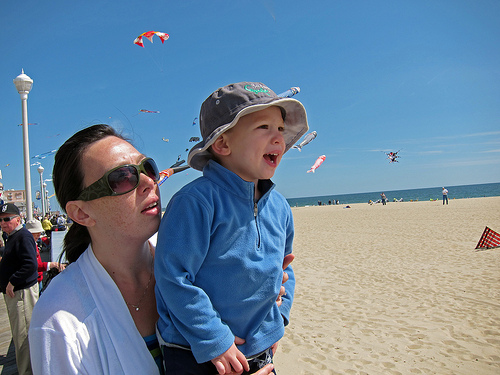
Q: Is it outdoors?
A: Yes, it is outdoors.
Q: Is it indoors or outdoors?
A: It is outdoors.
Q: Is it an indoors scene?
A: No, it is outdoors.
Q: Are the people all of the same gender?
A: No, they are both male and female.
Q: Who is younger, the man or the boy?
A: The boy is younger than the man.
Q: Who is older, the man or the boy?
A: The man is older than the boy.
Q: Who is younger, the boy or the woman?
A: The boy is younger than the woman.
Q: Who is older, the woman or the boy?
A: The woman is older than the boy.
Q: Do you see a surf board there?
A: No, there are no surfboards.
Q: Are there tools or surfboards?
A: No, there are no surfboards or tools.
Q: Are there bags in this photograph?
A: No, there are no bags.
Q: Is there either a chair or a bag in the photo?
A: No, there are no bags or chairs.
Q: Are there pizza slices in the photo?
A: No, there are no pizza slices.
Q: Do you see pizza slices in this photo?
A: No, there are no pizza slices.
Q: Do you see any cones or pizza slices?
A: No, there are no pizza slices or cones.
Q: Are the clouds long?
A: Yes, the clouds are long.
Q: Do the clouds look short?
A: No, the clouds are long.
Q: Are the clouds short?
A: No, the clouds are long.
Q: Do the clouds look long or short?
A: The clouds are long.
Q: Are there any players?
A: No, there are no players.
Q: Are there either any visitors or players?
A: No, there are no players or visitors.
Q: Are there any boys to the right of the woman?
A: Yes, there is a boy to the right of the woman.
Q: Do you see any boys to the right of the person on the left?
A: Yes, there is a boy to the right of the woman.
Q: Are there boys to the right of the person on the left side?
A: Yes, there is a boy to the right of the woman.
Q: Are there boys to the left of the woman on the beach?
A: No, the boy is to the right of the woman.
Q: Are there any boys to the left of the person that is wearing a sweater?
A: No, the boy is to the right of the woman.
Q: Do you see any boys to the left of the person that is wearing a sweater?
A: No, the boy is to the right of the woman.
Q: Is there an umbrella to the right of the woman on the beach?
A: No, there is a boy to the right of the woman.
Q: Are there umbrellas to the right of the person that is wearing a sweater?
A: No, there is a boy to the right of the woman.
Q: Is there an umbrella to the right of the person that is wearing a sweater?
A: No, there is a boy to the right of the woman.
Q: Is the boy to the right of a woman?
A: Yes, the boy is to the right of a woman.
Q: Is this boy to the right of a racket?
A: No, the boy is to the right of a woman.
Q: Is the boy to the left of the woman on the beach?
A: No, the boy is to the right of the woman.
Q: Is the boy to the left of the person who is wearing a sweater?
A: No, the boy is to the right of the woman.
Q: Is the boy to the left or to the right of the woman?
A: The boy is to the right of the woman.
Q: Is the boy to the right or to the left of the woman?
A: The boy is to the right of the woman.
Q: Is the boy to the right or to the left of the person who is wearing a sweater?
A: The boy is to the right of the woman.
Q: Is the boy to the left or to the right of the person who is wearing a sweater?
A: The boy is to the right of the woman.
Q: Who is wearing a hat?
A: The boy is wearing a hat.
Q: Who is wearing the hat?
A: The boy is wearing a hat.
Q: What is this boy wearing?
A: The boy is wearing a hat.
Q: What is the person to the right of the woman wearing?
A: The boy is wearing a hat.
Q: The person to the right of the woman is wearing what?
A: The boy is wearing a hat.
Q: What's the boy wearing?
A: The boy is wearing a hat.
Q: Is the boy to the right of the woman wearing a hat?
A: Yes, the boy is wearing a hat.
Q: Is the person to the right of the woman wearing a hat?
A: Yes, the boy is wearing a hat.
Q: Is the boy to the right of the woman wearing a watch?
A: No, the boy is wearing a hat.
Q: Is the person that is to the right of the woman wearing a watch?
A: No, the boy is wearing a hat.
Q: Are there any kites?
A: Yes, there is a kite.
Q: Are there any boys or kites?
A: Yes, there is a kite.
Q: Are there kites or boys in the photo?
A: Yes, there is a kite.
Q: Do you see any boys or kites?
A: Yes, there is a kite.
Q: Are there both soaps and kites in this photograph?
A: No, there is a kite but no soaps.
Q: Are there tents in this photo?
A: No, there are no tents.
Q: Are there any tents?
A: No, there are no tents.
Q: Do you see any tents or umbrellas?
A: No, there are no tents or umbrellas.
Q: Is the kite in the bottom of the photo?
A: No, the kite is in the top of the image.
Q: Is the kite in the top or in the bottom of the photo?
A: The kite is in the top of the image.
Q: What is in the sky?
A: The kite is in the sky.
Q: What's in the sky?
A: The kite is in the sky.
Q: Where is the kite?
A: The kite is in the sky.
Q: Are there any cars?
A: No, there are no cars.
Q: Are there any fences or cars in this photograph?
A: No, there are no cars or fences.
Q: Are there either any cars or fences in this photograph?
A: No, there are no cars or fences.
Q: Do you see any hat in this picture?
A: Yes, there is a hat.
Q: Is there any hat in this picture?
A: Yes, there is a hat.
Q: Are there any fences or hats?
A: Yes, there is a hat.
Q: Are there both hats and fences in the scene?
A: No, there is a hat but no fences.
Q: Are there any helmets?
A: No, there are no helmets.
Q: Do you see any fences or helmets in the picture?
A: No, there are no helmets or fences.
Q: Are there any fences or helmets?
A: No, there are no helmets or fences.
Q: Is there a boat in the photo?
A: No, there are no boats.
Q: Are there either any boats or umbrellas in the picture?
A: No, there are no boats or umbrellas.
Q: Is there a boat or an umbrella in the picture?
A: No, there are no boats or umbrellas.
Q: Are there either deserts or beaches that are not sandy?
A: No, there is a beach but it is sandy.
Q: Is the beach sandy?
A: Yes, the beach is sandy.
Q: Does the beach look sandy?
A: Yes, the beach is sandy.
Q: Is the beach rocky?
A: No, the beach is sandy.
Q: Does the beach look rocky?
A: No, the beach is sandy.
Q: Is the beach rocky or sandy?
A: The beach is sandy.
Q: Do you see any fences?
A: No, there are no fences.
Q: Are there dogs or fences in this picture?
A: No, there are no fences or dogs.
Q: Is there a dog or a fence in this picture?
A: No, there are no fences or dogs.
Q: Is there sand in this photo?
A: Yes, there is sand.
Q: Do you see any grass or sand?
A: Yes, there is sand.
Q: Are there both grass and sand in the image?
A: No, there is sand but no grass.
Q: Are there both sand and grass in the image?
A: No, there is sand but no grass.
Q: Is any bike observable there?
A: No, there are no bikes.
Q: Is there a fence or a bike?
A: No, there are no bikes or fences.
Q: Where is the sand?
A: The sand is on the beach.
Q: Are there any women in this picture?
A: Yes, there is a woman.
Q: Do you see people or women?
A: Yes, there is a woman.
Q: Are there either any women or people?
A: Yes, there is a woman.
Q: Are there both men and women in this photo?
A: Yes, there are both a woman and a man.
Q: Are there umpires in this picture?
A: No, there are no umpires.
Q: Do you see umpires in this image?
A: No, there are no umpires.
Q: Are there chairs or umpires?
A: No, there are no umpires or chairs.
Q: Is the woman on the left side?
A: Yes, the woman is on the left of the image.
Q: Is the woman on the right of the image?
A: No, the woman is on the left of the image.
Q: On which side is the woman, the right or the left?
A: The woman is on the left of the image.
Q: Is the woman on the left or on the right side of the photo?
A: The woman is on the left of the image.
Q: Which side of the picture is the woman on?
A: The woman is on the left of the image.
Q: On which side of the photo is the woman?
A: The woman is on the left of the image.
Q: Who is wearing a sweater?
A: The woman is wearing a sweater.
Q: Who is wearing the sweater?
A: The woman is wearing a sweater.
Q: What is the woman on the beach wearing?
A: The woman is wearing a sweater.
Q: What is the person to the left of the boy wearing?
A: The woman is wearing a sweater.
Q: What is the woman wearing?
A: The woman is wearing a sweater.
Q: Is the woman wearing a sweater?
A: Yes, the woman is wearing a sweater.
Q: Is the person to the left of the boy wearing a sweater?
A: Yes, the woman is wearing a sweater.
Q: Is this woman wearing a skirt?
A: No, the woman is wearing a sweater.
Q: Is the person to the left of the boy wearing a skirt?
A: No, the woman is wearing a sweater.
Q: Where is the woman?
A: The woman is on the beach.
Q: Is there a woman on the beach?
A: Yes, there is a woman on the beach.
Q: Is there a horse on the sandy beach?
A: No, there is a woman on the beach.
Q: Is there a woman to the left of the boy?
A: Yes, there is a woman to the left of the boy.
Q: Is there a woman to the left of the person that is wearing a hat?
A: Yes, there is a woman to the left of the boy.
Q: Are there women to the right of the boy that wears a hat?
A: No, the woman is to the left of the boy.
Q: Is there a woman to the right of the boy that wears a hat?
A: No, the woman is to the left of the boy.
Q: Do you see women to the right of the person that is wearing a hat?
A: No, the woman is to the left of the boy.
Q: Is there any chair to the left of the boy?
A: No, there is a woman to the left of the boy.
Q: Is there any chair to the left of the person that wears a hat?
A: No, there is a woman to the left of the boy.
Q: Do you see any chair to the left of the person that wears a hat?
A: No, there is a woman to the left of the boy.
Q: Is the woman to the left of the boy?
A: Yes, the woman is to the left of the boy.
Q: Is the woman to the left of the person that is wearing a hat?
A: Yes, the woman is to the left of the boy.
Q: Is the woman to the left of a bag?
A: No, the woman is to the left of the boy.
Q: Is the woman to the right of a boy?
A: No, the woman is to the left of a boy.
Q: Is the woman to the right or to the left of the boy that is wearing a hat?
A: The woman is to the left of the boy.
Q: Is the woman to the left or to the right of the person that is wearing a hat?
A: The woman is to the left of the boy.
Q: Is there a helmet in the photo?
A: No, there are no helmets.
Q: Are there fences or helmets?
A: No, there are no helmets or fences.